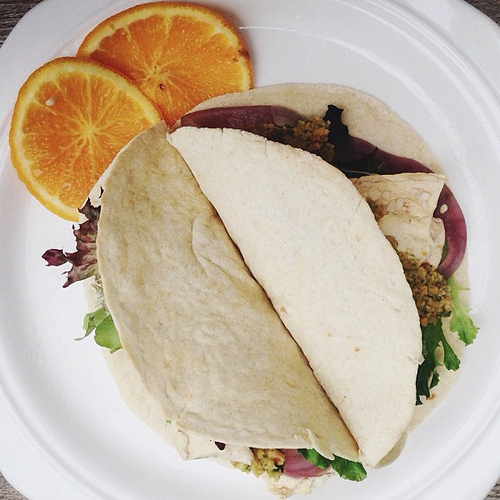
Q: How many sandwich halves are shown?
A: Two.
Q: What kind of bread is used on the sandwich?
A: Pita Bread.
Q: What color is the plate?
A: White.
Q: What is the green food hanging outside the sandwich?
A: Lettuce.